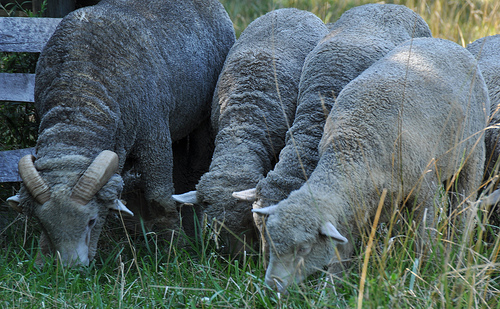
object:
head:
[6, 149, 134, 273]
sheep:
[251, 36, 490, 293]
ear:
[319, 221, 348, 245]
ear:
[251, 206, 276, 215]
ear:
[232, 188, 256, 201]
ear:
[109, 198, 135, 217]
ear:
[7, 195, 24, 214]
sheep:
[170, 8, 329, 269]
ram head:
[5, 0, 236, 272]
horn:
[18, 154, 52, 204]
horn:
[69, 150, 119, 206]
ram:
[6, 11, 235, 304]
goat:
[6, 1, 237, 274]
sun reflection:
[391, 51, 444, 82]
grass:
[2, 0, 499, 309]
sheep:
[231, 4, 432, 272]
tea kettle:
[236, 30, 491, 287]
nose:
[265, 281, 280, 290]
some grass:
[0, 203, 499, 308]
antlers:
[16, 150, 118, 202]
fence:
[0, 17, 64, 182]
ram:
[3, 2, 237, 270]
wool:
[106, 0, 231, 117]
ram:
[8, 144, 141, 204]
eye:
[88, 219, 95, 228]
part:
[157, 278, 181, 297]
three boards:
[0, 16, 63, 183]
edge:
[322, 226, 342, 244]